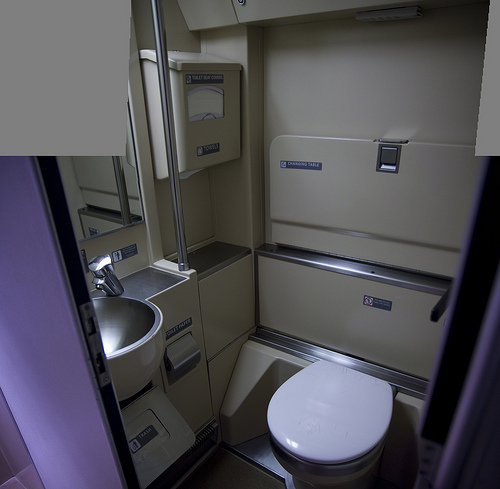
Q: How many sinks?
A: 1.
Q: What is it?
A: A restroom.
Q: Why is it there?
A: To use.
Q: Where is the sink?
A: On the wall.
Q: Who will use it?
A: People.